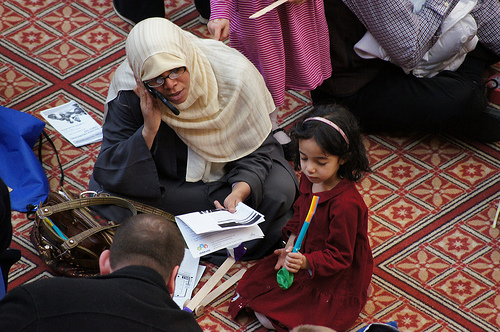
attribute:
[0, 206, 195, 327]
man — balding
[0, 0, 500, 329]
carpet — floral pattern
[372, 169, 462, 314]
carpet — red, beige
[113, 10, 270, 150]
burka — beige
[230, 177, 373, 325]
dress — red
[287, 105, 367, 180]
hair — black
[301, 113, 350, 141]
head band — pink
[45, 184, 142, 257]
handle — brown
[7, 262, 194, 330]
shirt — black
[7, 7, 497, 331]
pattern — distinct